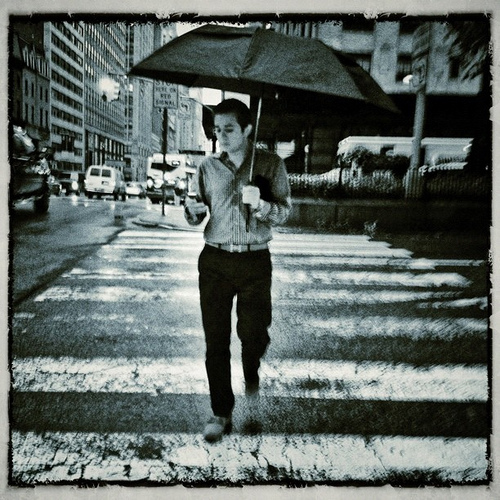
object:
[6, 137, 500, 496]
street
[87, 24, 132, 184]
buildings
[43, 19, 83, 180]
buildings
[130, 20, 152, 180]
buildings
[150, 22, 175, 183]
buildings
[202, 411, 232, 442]
shoe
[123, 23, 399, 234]
umbrella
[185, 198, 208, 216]
hand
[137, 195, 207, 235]
sidewalk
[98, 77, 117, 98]
trafficlight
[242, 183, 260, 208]
hand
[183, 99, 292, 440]
man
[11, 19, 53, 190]
building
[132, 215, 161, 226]
curb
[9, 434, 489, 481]
line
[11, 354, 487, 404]
line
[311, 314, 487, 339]
line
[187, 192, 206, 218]
cellphone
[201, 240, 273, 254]
belt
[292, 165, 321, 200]
fence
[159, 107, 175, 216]
street sign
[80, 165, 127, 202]
van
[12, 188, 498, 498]
road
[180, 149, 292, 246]
shirt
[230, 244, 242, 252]
buckle